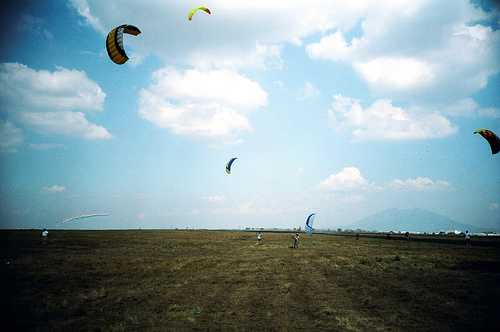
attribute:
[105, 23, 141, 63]
kite — yellow, blue, white, colorful, black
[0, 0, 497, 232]
sky — cloudy, blue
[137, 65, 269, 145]
cloud — white, fluffy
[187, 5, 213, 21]
kite — yellow, green, red, rainbow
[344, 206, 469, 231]
mountain — grey, distant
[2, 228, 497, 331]
field — large, open, brown, green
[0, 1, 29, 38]
corner — dark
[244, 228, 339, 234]
trees — distant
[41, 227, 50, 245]
man — playing, fun, enjoying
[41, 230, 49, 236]
shirt — white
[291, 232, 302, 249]
man — playing, fun, enjoying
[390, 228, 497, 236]
city — distant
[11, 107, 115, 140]
cloud — white, fluffy